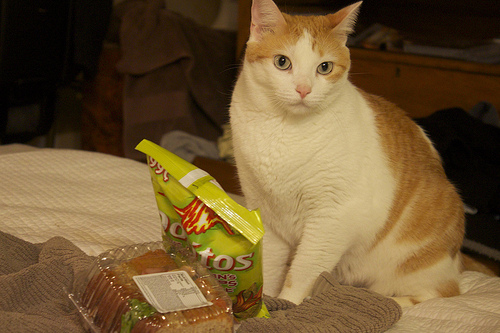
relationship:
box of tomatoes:
[63, 238, 238, 332] [86, 251, 232, 332]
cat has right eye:
[227, 2, 465, 308] [314, 59, 333, 74]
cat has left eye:
[227, 2, 465, 308] [275, 53, 291, 71]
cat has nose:
[227, 2, 465, 308] [294, 84, 312, 96]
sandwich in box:
[92, 249, 232, 331] [63, 238, 238, 332]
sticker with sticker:
[131, 270, 213, 313] [131, 270, 213, 313]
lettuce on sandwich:
[118, 298, 153, 332] [92, 249, 232, 331]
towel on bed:
[0, 230, 400, 332] [0, 142, 499, 332]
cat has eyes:
[227, 2, 465, 308] [273, 52, 335, 75]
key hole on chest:
[391, 64, 404, 78] [345, 3, 499, 120]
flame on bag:
[176, 197, 230, 236] [134, 135, 273, 320]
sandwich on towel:
[92, 249, 232, 331] [0, 230, 400, 332]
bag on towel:
[134, 135, 273, 320] [0, 230, 400, 332]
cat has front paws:
[227, 2, 465, 308] [252, 223, 343, 305]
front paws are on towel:
[252, 223, 343, 305] [0, 230, 400, 332]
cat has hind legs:
[227, 2, 465, 308] [359, 261, 457, 308]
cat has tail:
[227, 2, 465, 308] [444, 235, 467, 295]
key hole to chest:
[391, 64, 404, 78] [345, 3, 499, 120]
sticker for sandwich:
[131, 270, 213, 313] [92, 249, 232, 331]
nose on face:
[294, 84, 312, 96] [265, 32, 348, 112]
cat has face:
[227, 2, 465, 308] [265, 32, 348, 112]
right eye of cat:
[314, 59, 333, 74] [227, 2, 465, 308]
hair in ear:
[342, 10, 356, 36] [328, 1, 363, 44]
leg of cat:
[283, 224, 348, 305] [227, 2, 465, 308]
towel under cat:
[0, 230, 400, 332] [227, 2, 465, 308]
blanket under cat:
[1, 139, 499, 331] [227, 2, 465, 308]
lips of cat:
[286, 97, 315, 114] [227, 2, 465, 308]